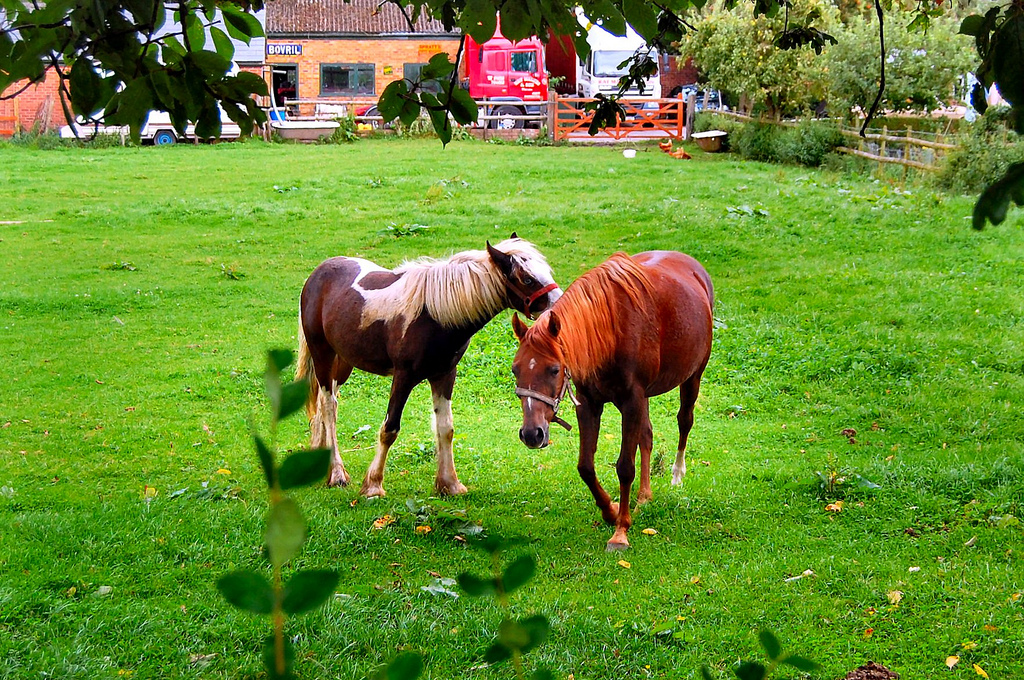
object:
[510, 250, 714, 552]
horse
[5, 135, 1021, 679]
grass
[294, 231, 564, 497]
horse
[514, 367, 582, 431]
bridle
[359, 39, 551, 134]
truck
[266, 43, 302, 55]
sign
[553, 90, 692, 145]
gate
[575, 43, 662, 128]
truck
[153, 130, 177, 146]
tire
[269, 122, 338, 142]
trough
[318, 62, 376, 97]
window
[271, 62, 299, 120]
door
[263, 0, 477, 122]
building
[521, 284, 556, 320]
halter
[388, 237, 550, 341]
mane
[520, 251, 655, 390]
mane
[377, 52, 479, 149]
leaves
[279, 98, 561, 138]
fence